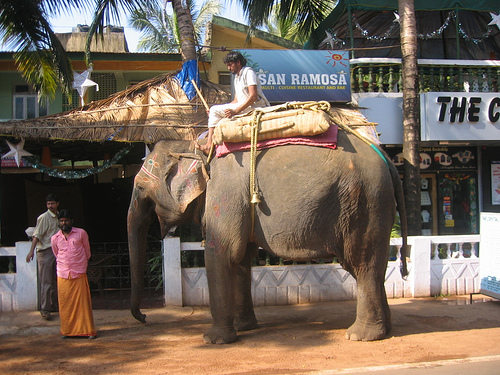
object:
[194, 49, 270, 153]
man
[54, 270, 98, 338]
skirt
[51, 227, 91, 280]
shirt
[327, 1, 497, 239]
tree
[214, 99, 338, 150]
saddle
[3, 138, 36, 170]
star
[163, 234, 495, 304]
fence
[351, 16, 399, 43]
tinsel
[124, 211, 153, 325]
trunk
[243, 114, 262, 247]
rope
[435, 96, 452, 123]
letters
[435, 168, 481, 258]
door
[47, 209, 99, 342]
person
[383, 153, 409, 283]
tail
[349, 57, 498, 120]
balcony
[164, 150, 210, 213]
ear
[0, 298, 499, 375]
ground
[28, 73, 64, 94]
leaf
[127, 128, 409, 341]
elephant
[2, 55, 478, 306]
store